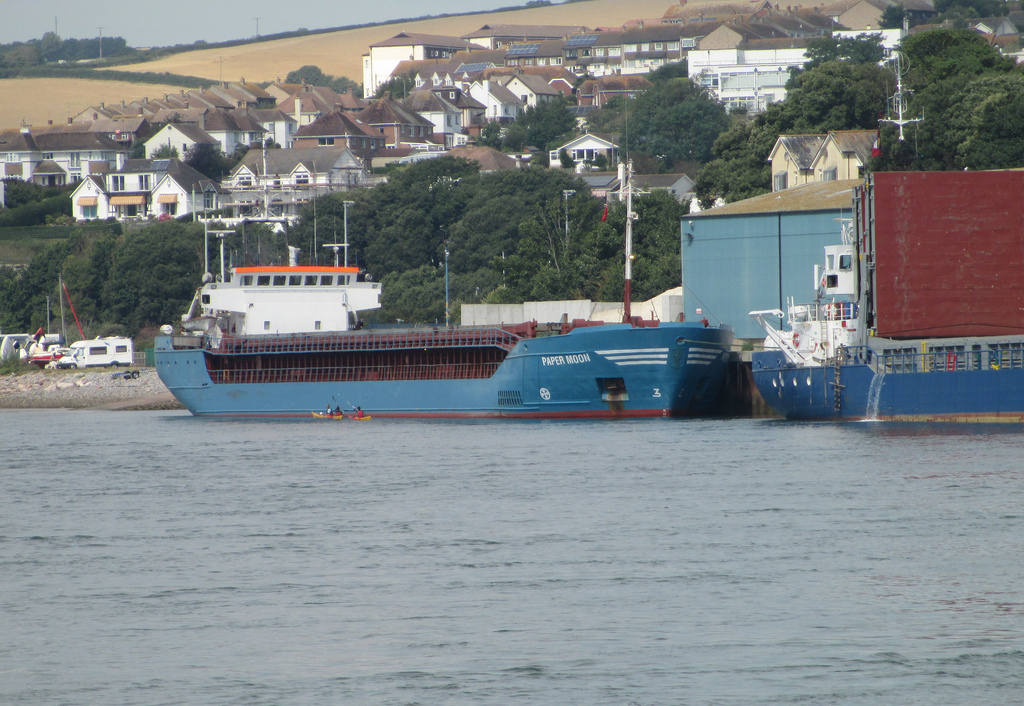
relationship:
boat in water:
[746, 297, 1022, 424] [18, 405, 1021, 701]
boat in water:
[152, 314, 737, 419] [18, 405, 1021, 701]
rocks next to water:
[3, 358, 175, 406] [18, 405, 1021, 701]